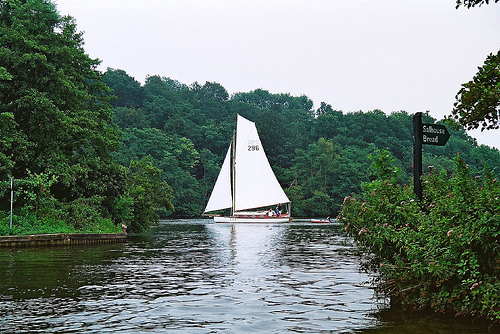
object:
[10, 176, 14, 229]
sticks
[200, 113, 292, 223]
boat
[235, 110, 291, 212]
sail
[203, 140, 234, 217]
sail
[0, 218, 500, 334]
water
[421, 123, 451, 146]
sign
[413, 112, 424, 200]
pole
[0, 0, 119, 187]
leaves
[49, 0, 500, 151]
clouds